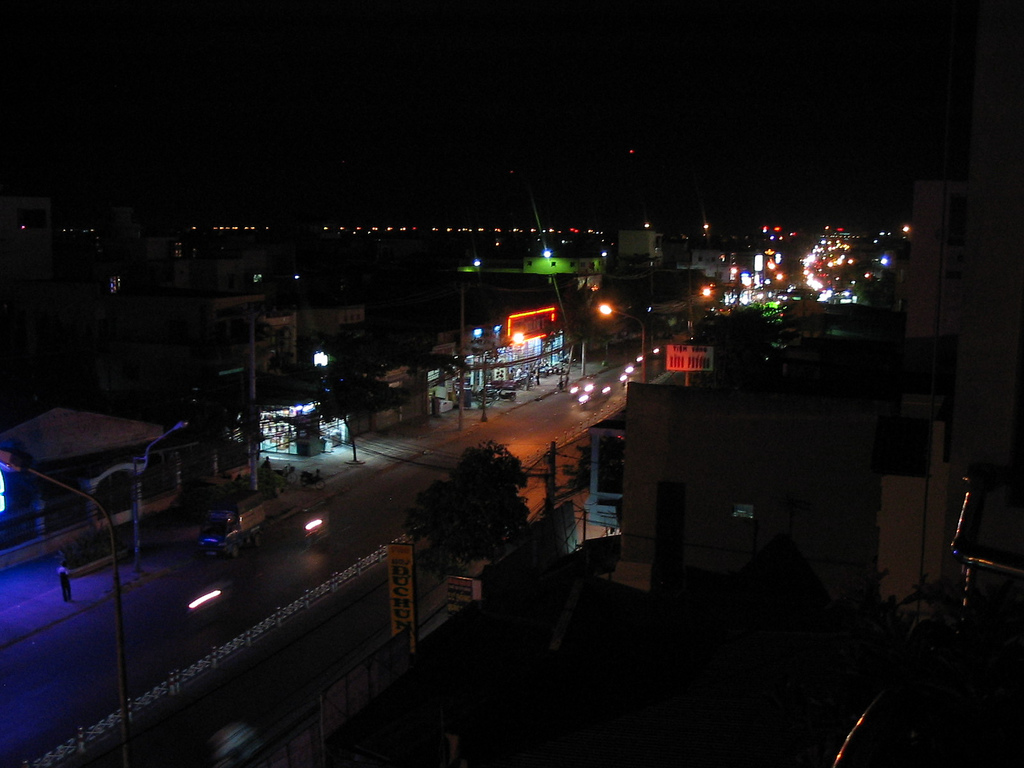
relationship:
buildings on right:
[342, 282, 1022, 766] [823, 31, 992, 714]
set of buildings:
[246, 303, 576, 463] [200, 282, 538, 635]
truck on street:
[191, 501, 275, 557] [16, 354, 645, 754]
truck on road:
[191, 501, 275, 557] [10, 354, 652, 761]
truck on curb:
[115, 501, 275, 577] [103, 494, 289, 575]